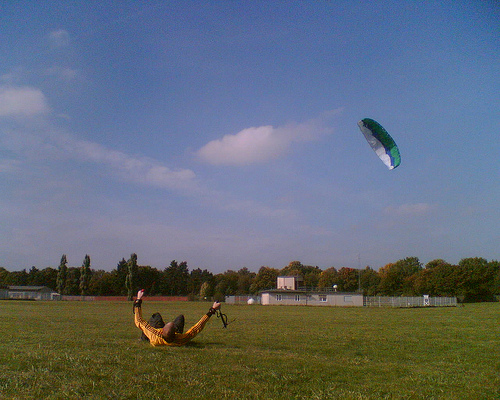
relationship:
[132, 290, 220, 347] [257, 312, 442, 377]
man on grass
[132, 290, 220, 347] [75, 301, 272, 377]
man on ground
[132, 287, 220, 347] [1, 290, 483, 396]
man on ground